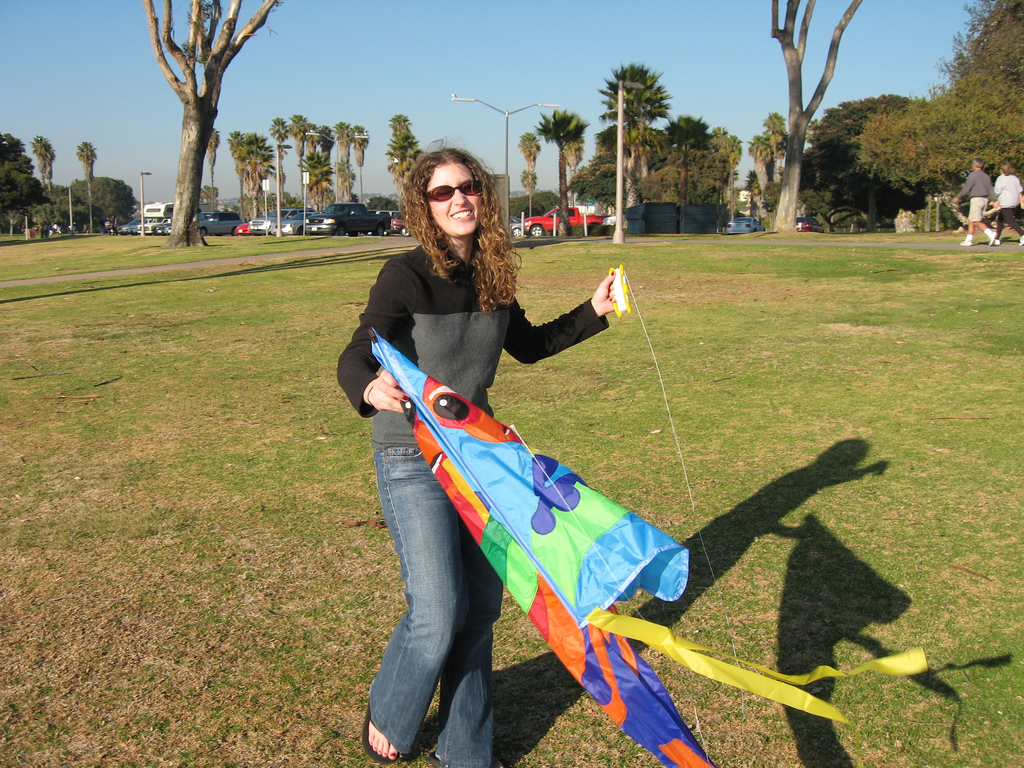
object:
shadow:
[777, 510, 1012, 766]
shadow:
[438, 438, 1008, 768]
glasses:
[424, 180, 484, 202]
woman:
[336, 150, 629, 768]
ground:
[520, 389, 1024, 768]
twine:
[610, 262, 682, 436]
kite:
[359, 326, 931, 768]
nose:
[454, 188, 470, 206]